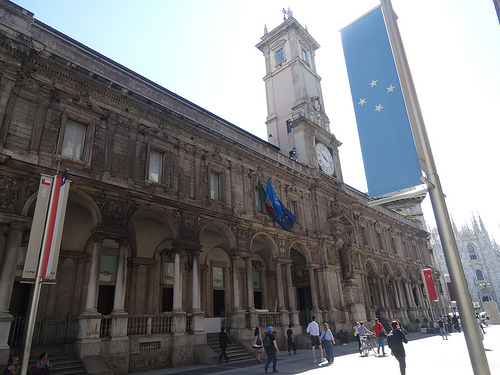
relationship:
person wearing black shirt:
[216, 326, 232, 366] [218, 332, 231, 346]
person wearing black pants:
[216, 326, 232, 366] [215, 341, 232, 365]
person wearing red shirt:
[371, 317, 388, 355] [371, 320, 386, 337]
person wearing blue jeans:
[371, 317, 388, 355] [374, 335, 386, 357]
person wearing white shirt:
[306, 314, 325, 367] [306, 321, 320, 337]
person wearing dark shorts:
[306, 314, 325, 367] [309, 333, 320, 347]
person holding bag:
[319, 321, 339, 366] [319, 332, 327, 344]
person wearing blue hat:
[261, 324, 283, 374] [264, 325, 275, 332]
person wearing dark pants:
[261, 324, 283, 374] [263, 344, 277, 374]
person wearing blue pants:
[319, 321, 339, 366] [322, 339, 336, 365]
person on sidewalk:
[261, 324, 283, 374] [149, 315, 463, 372]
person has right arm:
[261, 324, 283, 374] [271, 338, 282, 354]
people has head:
[384, 318, 411, 375] [389, 319, 402, 332]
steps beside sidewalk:
[203, 329, 257, 364] [149, 315, 463, 372]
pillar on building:
[76, 229, 110, 343] [0, 0, 454, 373]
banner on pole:
[337, 4, 428, 205] [379, 0, 495, 373]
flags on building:
[264, 174, 300, 231] [0, 0, 454, 373]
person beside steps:
[250, 324, 266, 365] [203, 329, 257, 364]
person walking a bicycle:
[355, 321, 374, 356] [357, 330, 383, 357]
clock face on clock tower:
[313, 142, 337, 178] [250, 7, 348, 186]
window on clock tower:
[272, 42, 287, 68] [250, 7, 348, 186]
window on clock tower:
[299, 47, 312, 66] [250, 7, 348, 186]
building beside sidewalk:
[0, 0, 454, 373] [149, 315, 463, 372]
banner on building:
[419, 265, 441, 305] [0, 0, 454, 373]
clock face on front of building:
[313, 142, 337, 178] [0, 0, 454, 373]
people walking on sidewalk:
[215, 318, 413, 372] [149, 315, 463, 372]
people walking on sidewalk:
[434, 308, 498, 341] [149, 315, 463, 372]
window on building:
[53, 109, 93, 167] [0, 0, 454, 373]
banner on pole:
[20, 172, 71, 287] [13, 163, 64, 373]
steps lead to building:
[203, 329, 257, 364] [0, 0, 454, 373]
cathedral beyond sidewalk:
[424, 213, 499, 326] [149, 315, 463, 372]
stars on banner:
[356, 77, 400, 117] [337, 4, 428, 205]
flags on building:
[252, 174, 300, 235] [0, 0, 454, 373]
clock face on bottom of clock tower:
[313, 142, 337, 178] [250, 7, 348, 186]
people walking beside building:
[215, 318, 413, 372] [0, 0, 454, 373]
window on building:
[141, 143, 164, 185] [0, 0, 454, 373]